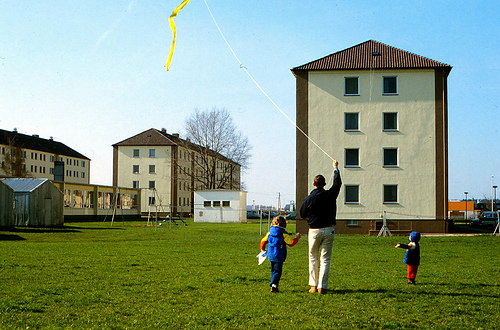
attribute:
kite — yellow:
[159, 0, 193, 74]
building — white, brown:
[289, 36, 452, 234]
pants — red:
[406, 263, 420, 283]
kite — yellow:
[162, 0, 186, 74]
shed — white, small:
[190, 184, 253, 229]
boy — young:
[366, 201, 454, 321]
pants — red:
[399, 257, 429, 283]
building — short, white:
[263, 32, 495, 303]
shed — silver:
[7, 176, 66, 233]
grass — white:
[135, 234, 232, 288]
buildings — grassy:
[0, 128, 252, 225]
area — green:
[4, 230, 498, 322]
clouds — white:
[56, 26, 178, 172]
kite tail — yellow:
[167, 2, 192, 70]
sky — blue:
[3, 1, 490, 215]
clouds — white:
[22, 47, 129, 149]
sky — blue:
[11, 5, 498, 178]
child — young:
[233, 182, 283, 296]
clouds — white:
[12, 69, 107, 138]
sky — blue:
[4, 3, 169, 113]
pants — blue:
[264, 256, 285, 290]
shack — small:
[187, 183, 249, 230]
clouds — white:
[42, 43, 206, 114]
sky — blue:
[14, 17, 468, 189]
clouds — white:
[33, 23, 248, 110]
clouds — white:
[50, 16, 260, 109]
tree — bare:
[181, 100, 253, 190]